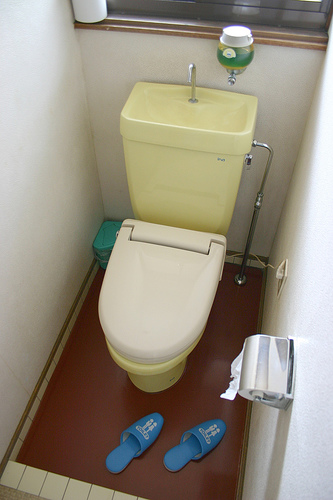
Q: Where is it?
A: This is at the bathroom.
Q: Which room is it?
A: It is a bathroom.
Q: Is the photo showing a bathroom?
A: Yes, it is showing a bathroom.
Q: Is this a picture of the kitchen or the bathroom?
A: It is showing the bathroom.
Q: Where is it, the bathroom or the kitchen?
A: It is the bathroom.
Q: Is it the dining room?
A: No, it is the bathroom.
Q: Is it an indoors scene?
A: Yes, it is indoors.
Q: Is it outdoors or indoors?
A: It is indoors.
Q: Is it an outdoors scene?
A: No, it is indoors.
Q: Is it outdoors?
A: No, it is indoors.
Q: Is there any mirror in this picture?
A: No, there are no mirrors.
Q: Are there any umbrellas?
A: No, there are no umbrellas.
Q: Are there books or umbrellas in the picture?
A: No, there are no umbrellas or books.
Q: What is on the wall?
A: The outlet is on the wall.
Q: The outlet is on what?
A: The outlet is on the wall.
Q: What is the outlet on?
A: The outlet is on the wall.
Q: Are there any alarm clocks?
A: No, there are no alarm clocks.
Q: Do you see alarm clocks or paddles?
A: No, there are no alarm clocks or paddles.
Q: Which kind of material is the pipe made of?
A: The pipe is made of metal.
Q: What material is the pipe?
A: The pipe is made of metal.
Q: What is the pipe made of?
A: The pipe is made of metal.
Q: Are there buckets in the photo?
A: No, there are no buckets.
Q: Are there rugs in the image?
A: No, there are no rugs.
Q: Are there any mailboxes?
A: No, there are no mailboxes.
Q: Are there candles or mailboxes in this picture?
A: No, there are no mailboxes or candles.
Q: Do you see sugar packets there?
A: No, there are no sugar packets.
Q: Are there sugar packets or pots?
A: No, there are no sugar packets or pots.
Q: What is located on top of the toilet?
A: The sink is on top of the toilet.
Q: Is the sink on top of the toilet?
A: Yes, the sink is on top of the toilet.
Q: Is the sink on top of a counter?
A: No, the sink is on top of the toilet.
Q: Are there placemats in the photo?
A: No, there are no placemats.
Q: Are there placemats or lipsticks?
A: No, there are no placemats or lipsticks.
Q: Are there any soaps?
A: Yes, there is a soap.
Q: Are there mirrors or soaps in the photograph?
A: Yes, there is a soap.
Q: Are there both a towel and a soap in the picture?
A: No, there is a soap but no towels.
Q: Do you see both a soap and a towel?
A: No, there is a soap but no towels.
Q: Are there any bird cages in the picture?
A: No, there are no bird cages.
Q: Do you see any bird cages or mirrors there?
A: No, there are no bird cages or mirrors.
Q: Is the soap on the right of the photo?
A: Yes, the soap is on the right of the image.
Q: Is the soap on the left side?
A: No, the soap is on the right of the image.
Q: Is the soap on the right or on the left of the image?
A: The soap is on the right of the image.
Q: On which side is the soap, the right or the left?
A: The soap is on the right of the image.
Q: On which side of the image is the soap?
A: The soap is on the right of the image.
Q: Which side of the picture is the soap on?
A: The soap is on the right of the image.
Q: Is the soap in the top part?
A: Yes, the soap is in the top of the image.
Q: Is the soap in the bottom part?
A: No, the soap is in the top of the image.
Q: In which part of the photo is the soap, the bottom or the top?
A: The soap is in the top of the image.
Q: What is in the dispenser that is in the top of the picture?
A: The soap is in the dispenser.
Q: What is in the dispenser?
A: The soap is in the dispenser.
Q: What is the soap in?
A: The soap is in the dispenser.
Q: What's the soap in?
A: The soap is in the dispenser.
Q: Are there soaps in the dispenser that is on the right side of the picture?
A: Yes, there is a soap in the dispenser.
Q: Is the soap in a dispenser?
A: Yes, the soap is in a dispenser.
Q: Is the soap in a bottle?
A: No, the soap is in a dispenser.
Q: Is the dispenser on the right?
A: Yes, the dispenser is on the right of the image.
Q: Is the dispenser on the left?
A: No, the dispenser is on the right of the image.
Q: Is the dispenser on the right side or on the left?
A: The dispenser is on the right of the image.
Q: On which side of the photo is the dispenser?
A: The dispenser is on the right of the image.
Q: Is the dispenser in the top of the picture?
A: Yes, the dispenser is in the top of the image.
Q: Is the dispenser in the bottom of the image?
A: No, the dispenser is in the top of the image.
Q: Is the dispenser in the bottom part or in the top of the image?
A: The dispenser is in the top of the image.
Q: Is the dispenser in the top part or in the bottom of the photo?
A: The dispenser is in the top of the image.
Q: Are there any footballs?
A: No, there are no footballs.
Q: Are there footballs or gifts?
A: No, there are no footballs or gifts.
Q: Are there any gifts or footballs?
A: No, there are no footballs or gifts.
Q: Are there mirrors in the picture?
A: No, there are no mirrors.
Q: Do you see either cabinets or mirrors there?
A: No, there are no mirrors or cabinets.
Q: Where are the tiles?
A: The tiles are on the floor.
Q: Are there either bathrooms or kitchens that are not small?
A: No, there is a bathroom but it is small.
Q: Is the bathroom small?
A: Yes, the bathroom is small.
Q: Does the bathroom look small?
A: Yes, the bathroom is small.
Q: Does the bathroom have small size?
A: Yes, the bathroom is small.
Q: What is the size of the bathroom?
A: The bathroom is small.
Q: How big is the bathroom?
A: The bathroom is small.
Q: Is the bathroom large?
A: No, the bathroom is small.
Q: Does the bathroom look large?
A: No, the bathroom is small.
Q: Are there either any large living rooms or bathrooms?
A: No, there is a bathroom but it is small.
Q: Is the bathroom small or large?
A: The bathroom is small.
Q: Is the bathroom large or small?
A: The bathroom is small.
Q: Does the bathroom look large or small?
A: The bathroom is small.